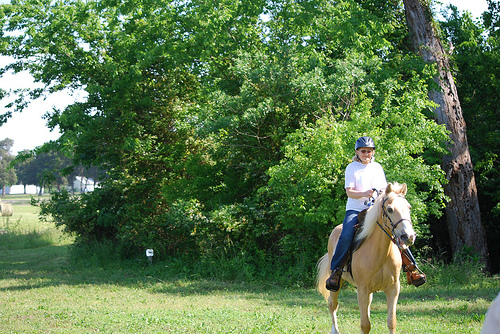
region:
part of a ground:
[211, 278, 248, 325]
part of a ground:
[201, 299, 226, 324]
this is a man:
[316, 115, 386, 202]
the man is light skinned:
[358, 148, 370, 159]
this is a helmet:
[343, 132, 379, 149]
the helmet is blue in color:
[353, 129, 380, 145]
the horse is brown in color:
[356, 254, 394, 294]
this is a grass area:
[74, 281, 181, 315]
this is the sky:
[5, 105, 47, 148]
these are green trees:
[77, 44, 312, 257]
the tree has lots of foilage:
[98, 64, 298, 253]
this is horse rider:
[338, 161, 469, 326]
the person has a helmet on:
[337, 132, 384, 168]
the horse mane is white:
[359, 198, 398, 245]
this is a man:
[339, 133, 393, 193]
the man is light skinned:
[358, 149, 371, 168]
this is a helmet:
[354, 133, 378, 144]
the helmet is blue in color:
[358, 135, 375, 147]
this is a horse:
[354, 216, 418, 323]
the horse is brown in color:
[357, 251, 386, 294]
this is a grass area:
[106, 265, 185, 310]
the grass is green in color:
[103, 265, 163, 314]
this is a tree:
[181, 15, 351, 316]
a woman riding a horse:
[326, 136, 426, 292]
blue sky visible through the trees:
[4, 2, 497, 155]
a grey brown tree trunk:
[401, 1, 488, 265]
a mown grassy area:
[2, 245, 499, 331]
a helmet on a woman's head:
[354, 134, 377, 151]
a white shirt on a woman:
[345, 159, 386, 211]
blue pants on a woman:
[330, 209, 362, 269]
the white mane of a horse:
[356, 192, 381, 245]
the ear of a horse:
[397, 181, 410, 197]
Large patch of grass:
[57, 273, 139, 325]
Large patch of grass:
[16, 268, 92, 328]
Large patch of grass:
[46, 288, 126, 331]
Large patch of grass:
[17, 272, 107, 331]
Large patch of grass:
[49, 281, 146, 332]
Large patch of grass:
[11, 268, 104, 325]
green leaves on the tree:
[243, 153, 283, 195]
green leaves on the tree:
[253, 187, 302, 238]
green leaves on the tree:
[373, 125, 428, 160]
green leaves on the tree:
[123, 159, 206, 223]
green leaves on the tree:
[126, 91, 175, 144]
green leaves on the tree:
[146, 98, 239, 163]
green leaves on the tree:
[69, 181, 128, 228]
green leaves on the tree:
[229, 63, 283, 99]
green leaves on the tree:
[266, 53, 396, 138]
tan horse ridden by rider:
[317, 117, 417, 317]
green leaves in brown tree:
[84, 97, 136, 139]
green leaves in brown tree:
[209, 192, 243, 212]